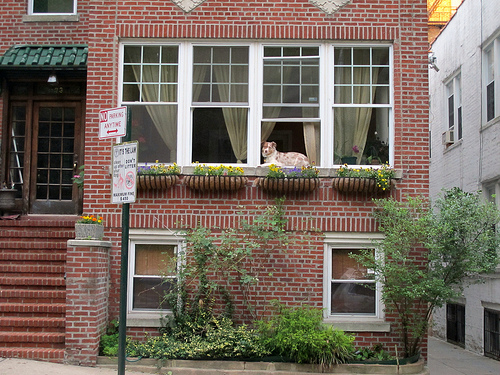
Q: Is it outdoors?
A: Yes, it is outdoors.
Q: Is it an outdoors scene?
A: Yes, it is outdoors.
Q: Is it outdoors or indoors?
A: It is outdoors.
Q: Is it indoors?
A: No, it is outdoors.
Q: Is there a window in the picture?
A: Yes, there is a window.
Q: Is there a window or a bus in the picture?
A: Yes, there is a window.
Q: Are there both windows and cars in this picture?
A: No, there is a window but no cars.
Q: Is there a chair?
A: No, there are no chairs.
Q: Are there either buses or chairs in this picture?
A: No, there are no chairs or buses.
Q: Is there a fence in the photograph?
A: No, there are no fences.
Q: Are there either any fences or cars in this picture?
A: No, there are no fences or cars.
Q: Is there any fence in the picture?
A: No, there are no fences.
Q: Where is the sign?
A: The sign is on the street.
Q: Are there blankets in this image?
A: No, there are no blankets.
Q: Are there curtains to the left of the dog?
A: Yes, there are curtains to the left of the dog.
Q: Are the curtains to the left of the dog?
A: Yes, the curtains are to the left of the dog.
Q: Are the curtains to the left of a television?
A: No, the curtains are to the left of the dog.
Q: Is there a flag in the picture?
A: No, there are no flags.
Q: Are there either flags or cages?
A: No, there are no flags or cages.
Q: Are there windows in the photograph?
A: Yes, there is a window.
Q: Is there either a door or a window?
A: Yes, there is a window.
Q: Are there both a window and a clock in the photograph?
A: No, there is a window but no clocks.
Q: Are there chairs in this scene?
A: No, there are no chairs.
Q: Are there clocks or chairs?
A: No, there are no chairs or clocks.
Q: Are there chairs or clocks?
A: No, there are no chairs or clocks.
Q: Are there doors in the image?
A: Yes, there is a door.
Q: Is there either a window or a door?
A: Yes, there is a door.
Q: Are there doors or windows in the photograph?
A: Yes, there is a door.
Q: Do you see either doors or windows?
A: Yes, there is a door.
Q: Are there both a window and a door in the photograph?
A: Yes, there are both a door and a window.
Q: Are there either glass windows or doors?
A: Yes, there is a glass door.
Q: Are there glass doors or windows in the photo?
A: Yes, there is a glass door.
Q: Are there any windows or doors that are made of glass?
A: Yes, the door is made of glass.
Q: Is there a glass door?
A: Yes, there is a door that is made of glass.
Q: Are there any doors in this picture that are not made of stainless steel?
A: Yes, there is a door that is made of glass.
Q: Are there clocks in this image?
A: No, there are no clocks.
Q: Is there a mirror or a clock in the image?
A: No, there are no clocks or mirrors.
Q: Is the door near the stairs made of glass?
A: Yes, the door is made of glass.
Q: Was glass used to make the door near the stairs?
A: Yes, the door is made of glass.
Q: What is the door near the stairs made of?
A: The door is made of glass.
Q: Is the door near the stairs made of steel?
A: No, the door is made of glass.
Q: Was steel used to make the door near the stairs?
A: No, the door is made of glass.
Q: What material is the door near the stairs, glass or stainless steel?
A: The door is made of glass.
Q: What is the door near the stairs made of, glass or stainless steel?
A: The door is made of glass.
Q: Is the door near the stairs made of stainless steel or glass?
A: The door is made of glass.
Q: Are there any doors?
A: Yes, there is a door.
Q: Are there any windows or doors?
A: Yes, there is a door.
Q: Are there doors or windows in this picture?
A: Yes, there is a door.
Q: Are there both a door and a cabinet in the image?
A: No, there is a door but no cabinets.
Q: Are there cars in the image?
A: No, there are no cars.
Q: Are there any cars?
A: No, there are no cars.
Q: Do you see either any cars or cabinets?
A: No, there are no cars or cabinets.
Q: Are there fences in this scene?
A: No, there are no fences.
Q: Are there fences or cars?
A: No, there are no fences or cars.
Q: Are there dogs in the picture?
A: Yes, there is a dog.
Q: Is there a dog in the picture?
A: Yes, there is a dog.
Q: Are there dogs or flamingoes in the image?
A: Yes, there is a dog.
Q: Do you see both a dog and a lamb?
A: No, there is a dog but no lambs.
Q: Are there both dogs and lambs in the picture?
A: No, there is a dog but no lambs.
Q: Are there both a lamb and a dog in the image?
A: No, there is a dog but no lambs.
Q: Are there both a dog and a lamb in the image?
A: No, there is a dog but no lambs.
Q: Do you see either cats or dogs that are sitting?
A: Yes, the dog is sitting.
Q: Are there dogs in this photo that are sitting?
A: Yes, there is a dog that is sitting.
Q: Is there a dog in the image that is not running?
A: Yes, there is a dog that is sitting.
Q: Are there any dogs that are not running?
A: Yes, there is a dog that is sitting.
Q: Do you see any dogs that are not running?
A: Yes, there is a dog that is sitting .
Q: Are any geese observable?
A: No, there are no geese.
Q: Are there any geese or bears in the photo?
A: No, there are no geese or bears.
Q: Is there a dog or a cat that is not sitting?
A: No, there is a dog but it is sitting.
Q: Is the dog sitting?
A: Yes, the dog is sitting.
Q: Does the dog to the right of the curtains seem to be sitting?
A: Yes, the dog is sitting.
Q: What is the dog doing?
A: The dog is sitting.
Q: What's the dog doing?
A: The dog is sitting.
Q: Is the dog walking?
A: No, the dog is sitting.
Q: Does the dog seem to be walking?
A: No, the dog is sitting.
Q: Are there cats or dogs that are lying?
A: No, there is a dog but it is sitting.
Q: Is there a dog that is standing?
A: No, there is a dog but it is sitting.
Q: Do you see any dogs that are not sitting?
A: No, there is a dog but it is sitting.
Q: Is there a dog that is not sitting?
A: No, there is a dog but it is sitting.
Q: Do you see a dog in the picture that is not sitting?
A: No, there is a dog but it is sitting.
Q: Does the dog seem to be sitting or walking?
A: The dog is sitting.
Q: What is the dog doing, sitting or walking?
A: The dog is sitting.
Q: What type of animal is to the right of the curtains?
A: The animal is a dog.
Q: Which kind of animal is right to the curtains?
A: The animal is a dog.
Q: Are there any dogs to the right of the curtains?
A: Yes, there is a dog to the right of the curtains.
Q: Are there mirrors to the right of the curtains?
A: No, there is a dog to the right of the curtains.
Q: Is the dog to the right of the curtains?
A: Yes, the dog is to the right of the curtains.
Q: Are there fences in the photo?
A: No, there are no fences.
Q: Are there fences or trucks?
A: No, there are no fences or trucks.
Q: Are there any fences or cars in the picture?
A: No, there are no cars or fences.